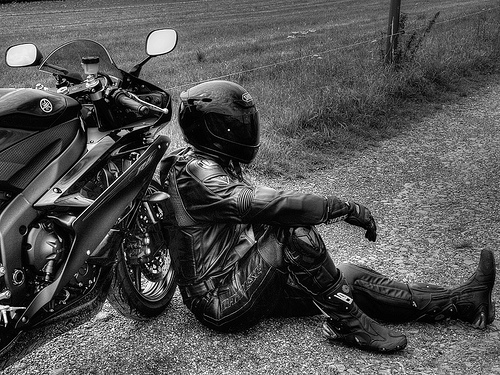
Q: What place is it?
A: It is a road.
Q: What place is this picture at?
A: It is at the road.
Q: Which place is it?
A: It is a road.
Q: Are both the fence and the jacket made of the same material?
A: No, the fence is made of wood and the jacket is made of metal.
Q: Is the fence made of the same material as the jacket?
A: No, the fence is made of wood and the jacket is made of metal.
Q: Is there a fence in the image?
A: Yes, there is a fence.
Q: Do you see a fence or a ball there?
A: Yes, there is a fence.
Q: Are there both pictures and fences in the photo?
A: No, there is a fence but no pictures.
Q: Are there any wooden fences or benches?
A: Yes, there is a wood fence.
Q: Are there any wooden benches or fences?
A: Yes, there is a wood fence.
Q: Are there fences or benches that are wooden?
A: Yes, the fence is wooden.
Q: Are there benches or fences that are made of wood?
A: Yes, the fence is made of wood.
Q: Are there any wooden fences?
A: Yes, there is a wood fence.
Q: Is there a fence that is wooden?
A: Yes, there is a fence that is wooden.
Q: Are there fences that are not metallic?
A: Yes, there is a wooden fence.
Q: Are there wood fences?
A: Yes, there is a fence that is made of wood.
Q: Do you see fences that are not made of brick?
A: Yes, there is a fence that is made of wood.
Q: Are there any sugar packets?
A: No, there are no sugar packets.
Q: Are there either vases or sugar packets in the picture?
A: No, there are no sugar packets or vases.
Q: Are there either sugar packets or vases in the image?
A: No, there are no sugar packets or vases.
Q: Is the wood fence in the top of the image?
A: Yes, the fence is in the top of the image.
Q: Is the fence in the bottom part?
A: No, the fence is in the top of the image.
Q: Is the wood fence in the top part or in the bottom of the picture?
A: The fence is in the top of the image.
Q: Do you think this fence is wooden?
A: Yes, the fence is wooden.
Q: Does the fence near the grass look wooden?
A: Yes, the fence is wooden.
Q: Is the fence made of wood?
A: Yes, the fence is made of wood.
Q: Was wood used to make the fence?
A: Yes, the fence is made of wood.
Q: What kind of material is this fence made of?
A: The fence is made of wood.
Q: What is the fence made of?
A: The fence is made of wood.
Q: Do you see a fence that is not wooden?
A: No, there is a fence but it is wooden.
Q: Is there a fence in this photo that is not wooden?
A: No, there is a fence but it is wooden.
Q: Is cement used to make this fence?
A: No, the fence is made of wood.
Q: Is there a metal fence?
A: No, there is a fence but it is made of wood.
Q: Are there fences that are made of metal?
A: No, there is a fence but it is made of wood.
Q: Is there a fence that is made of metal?
A: No, there is a fence but it is made of wood.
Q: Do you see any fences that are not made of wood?
A: No, there is a fence but it is made of wood.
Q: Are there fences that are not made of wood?
A: No, there is a fence but it is made of wood.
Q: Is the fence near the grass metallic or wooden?
A: The fence is wooden.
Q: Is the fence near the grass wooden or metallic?
A: The fence is wooden.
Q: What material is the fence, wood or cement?
A: The fence is made of wood.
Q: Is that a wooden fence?
A: Yes, that is a wooden fence.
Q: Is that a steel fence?
A: No, that is a wooden fence.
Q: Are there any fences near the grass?
A: Yes, there is a fence near the grass.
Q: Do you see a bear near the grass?
A: No, there is a fence near the grass.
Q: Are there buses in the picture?
A: No, there are no buses.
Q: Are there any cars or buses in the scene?
A: No, there are no buses or cars.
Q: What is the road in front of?
A: The road is in front of the grass.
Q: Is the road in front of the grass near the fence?
A: Yes, the road is in front of the grass.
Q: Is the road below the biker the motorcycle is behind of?
A: Yes, the road is below the biker.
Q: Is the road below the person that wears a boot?
A: Yes, the road is below the biker.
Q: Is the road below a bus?
A: No, the road is below the biker.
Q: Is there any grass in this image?
A: Yes, there is grass.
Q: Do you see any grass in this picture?
A: Yes, there is grass.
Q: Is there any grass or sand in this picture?
A: Yes, there is grass.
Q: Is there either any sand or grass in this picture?
A: Yes, there is grass.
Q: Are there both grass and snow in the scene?
A: No, there is grass but no snow.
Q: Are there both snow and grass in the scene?
A: No, there is grass but no snow.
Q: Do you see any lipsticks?
A: No, there are no lipsticks.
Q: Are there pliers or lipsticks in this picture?
A: No, there are no lipsticks or pliers.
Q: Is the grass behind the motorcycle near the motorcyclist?
A: Yes, the grass is behind the motorcycle.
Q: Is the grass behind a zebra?
A: No, the grass is behind the motorcycle.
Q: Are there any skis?
A: No, there are no skis.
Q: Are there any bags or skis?
A: No, there are no skis or bags.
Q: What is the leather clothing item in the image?
A: The clothing item is a jacket.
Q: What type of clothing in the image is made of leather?
A: The clothing is a jacket.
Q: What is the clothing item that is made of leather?
A: The clothing item is a jacket.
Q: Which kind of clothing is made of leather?
A: The clothing is a jacket.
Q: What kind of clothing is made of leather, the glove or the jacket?
A: The jacket is made of leather.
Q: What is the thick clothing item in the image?
A: The clothing item is a jacket.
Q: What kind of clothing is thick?
A: The clothing is a jacket.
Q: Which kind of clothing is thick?
A: The clothing is a jacket.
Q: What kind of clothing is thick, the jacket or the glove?
A: The jacket is thick.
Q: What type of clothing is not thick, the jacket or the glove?
A: The glove is not thick.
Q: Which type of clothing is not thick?
A: The clothing is a glove.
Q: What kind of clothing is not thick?
A: The clothing is a glove.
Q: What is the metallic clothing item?
A: The clothing item is a jacket.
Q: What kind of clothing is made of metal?
A: The clothing is a jacket.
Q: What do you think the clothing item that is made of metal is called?
A: The clothing item is a jacket.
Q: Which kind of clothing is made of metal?
A: The clothing is a jacket.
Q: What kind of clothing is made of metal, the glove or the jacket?
A: The jacket is made of metal.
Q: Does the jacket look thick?
A: Yes, the jacket is thick.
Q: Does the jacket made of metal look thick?
A: Yes, the jacket is thick.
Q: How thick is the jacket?
A: The jacket is thick.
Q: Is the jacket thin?
A: No, the jacket is thick.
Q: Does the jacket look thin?
A: No, the jacket is thick.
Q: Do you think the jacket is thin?
A: No, the jacket is thick.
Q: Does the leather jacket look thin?
A: No, the jacket is thick.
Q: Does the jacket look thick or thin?
A: The jacket is thick.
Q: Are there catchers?
A: No, there are no catchers.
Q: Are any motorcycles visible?
A: Yes, there is a motorcycle.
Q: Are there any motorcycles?
A: Yes, there is a motorcycle.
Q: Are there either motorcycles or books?
A: Yes, there is a motorcycle.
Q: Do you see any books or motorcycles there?
A: Yes, there is a motorcycle.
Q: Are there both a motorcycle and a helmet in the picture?
A: Yes, there are both a motorcycle and a helmet.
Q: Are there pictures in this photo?
A: No, there are no pictures.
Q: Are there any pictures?
A: No, there are no pictures.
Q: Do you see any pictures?
A: No, there are no pictures.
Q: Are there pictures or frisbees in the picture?
A: No, there are no pictures or frisbees.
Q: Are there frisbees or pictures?
A: No, there are no pictures or frisbees.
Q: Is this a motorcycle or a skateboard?
A: This is a motorcycle.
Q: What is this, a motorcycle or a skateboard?
A: This is a motorcycle.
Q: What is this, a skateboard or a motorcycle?
A: This is a motorcycle.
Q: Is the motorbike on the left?
A: Yes, the motorbike is on the left of the image.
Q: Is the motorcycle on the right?
A: No, the motorcycle is on the left of the image.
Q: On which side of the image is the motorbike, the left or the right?
A: The motorbike is on the left of the image.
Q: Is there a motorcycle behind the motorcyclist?
A: Yes, there is a motorcycle behind the motorcyclist.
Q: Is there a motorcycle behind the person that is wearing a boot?
A: Yes, there is a motorcycle behind the motorcyclist.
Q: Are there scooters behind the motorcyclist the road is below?
A: No, there is a motorcycle behind the motorcyclist.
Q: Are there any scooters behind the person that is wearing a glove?
A: No, there is a motorcycle behind the motorcyclist.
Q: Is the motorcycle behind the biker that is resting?
A: Yes, the motorcycle is behind the biker.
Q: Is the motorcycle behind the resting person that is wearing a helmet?
A: Yes, the motorcycle is behind the biker.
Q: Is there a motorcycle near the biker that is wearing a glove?
A: Yes, there is a motorcycle near the motorcyclist.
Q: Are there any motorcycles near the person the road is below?
A: Yes, there is a motorcycle near the motorcyclist.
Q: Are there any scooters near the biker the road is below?
A: No, there is a motorcycle near the motorcyclist.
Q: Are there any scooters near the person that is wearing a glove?
A: No, there is a motorcycle near the motorcyclist.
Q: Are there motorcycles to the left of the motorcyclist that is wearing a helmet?
A: Yes, there is a motorcycle to the left of the biker.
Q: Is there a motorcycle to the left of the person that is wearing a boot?
A: Yes, there is a motorcycle to the left of the biker.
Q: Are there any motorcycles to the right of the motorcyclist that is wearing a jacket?
A: No, the motorcycle is to the left of the motorcyclist.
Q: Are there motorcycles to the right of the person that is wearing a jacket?
A: No, the motorcycle is to the left of the motorcyclist.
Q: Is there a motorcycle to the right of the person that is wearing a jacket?
A: No, the motorcycle is to the left of the motorcyclist.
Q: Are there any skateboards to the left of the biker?
A: No, there is a motorcycle to the left of the biker.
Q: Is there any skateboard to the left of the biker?
A: No, there is a motorcycle to the left of the biker.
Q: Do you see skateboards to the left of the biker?
A: No, there is a motorcycle to the left of the biker.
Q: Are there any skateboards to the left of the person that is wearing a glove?
A: No, there is a motorcycle to the left of the biker.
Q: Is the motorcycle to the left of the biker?
A: Yes, the motorcycle is to the left of the biker.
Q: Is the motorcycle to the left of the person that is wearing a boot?
A: Yes, the motorcycle is to the left of the biker.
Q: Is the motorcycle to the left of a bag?
A: No, the motorcycle is to the left of the biker.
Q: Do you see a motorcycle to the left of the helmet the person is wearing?
A: Yes, there is a motorcycle to the left of the helmet.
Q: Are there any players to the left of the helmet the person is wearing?
A: No, there is a motorcycle to the left of the helmet.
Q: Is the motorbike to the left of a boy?
A: No, the motorbike is to the left of the helmet.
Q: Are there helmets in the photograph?
A: Yes, there is a helmet.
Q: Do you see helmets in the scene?
A: Yes, there is a helmet.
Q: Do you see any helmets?
A: Yes, there is a helmet.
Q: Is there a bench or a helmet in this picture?
A: Yes, there is a helmet.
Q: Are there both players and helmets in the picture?
A: No, there is a helmet but no players.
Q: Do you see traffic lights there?
A: No, there are no traffic lights.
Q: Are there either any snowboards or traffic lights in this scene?
A: No, there are no traffic lights or snowboards.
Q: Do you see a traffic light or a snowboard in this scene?
A: No, there are no traffic lights or snowboards.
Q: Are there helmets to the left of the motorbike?
A: No, the helmet is to the right of the motorbike.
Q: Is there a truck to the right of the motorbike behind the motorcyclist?
A: No, there is a helmet to the right of the motorcycle.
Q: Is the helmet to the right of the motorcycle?
A: Yes, the helmet is to the right of the motorcycle.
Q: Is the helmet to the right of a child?
A: No, the helmet is to the right of the motorcycle.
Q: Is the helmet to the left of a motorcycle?
A: No, the helmet is to the right of a motorcycle.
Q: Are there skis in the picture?
A: No, there are no skis.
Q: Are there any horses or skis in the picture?
A: No, there are no skis or horses.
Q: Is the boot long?
A: Yes, the boot is long.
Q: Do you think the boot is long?
A: Yes, the boot is long.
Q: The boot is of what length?
A: The boot is long.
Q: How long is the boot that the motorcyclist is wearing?
A: The boot is long.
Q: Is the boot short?
A: No, the boot is long.